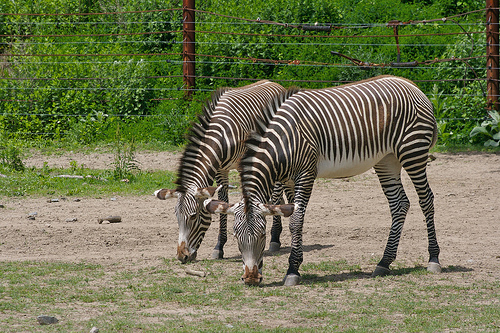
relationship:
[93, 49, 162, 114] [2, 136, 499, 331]
shrub on ground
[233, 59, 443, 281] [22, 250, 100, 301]
zebra grazing on grass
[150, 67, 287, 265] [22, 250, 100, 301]
zebra grazing on grass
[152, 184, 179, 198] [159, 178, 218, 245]
ear on head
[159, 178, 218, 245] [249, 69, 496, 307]
head of zebra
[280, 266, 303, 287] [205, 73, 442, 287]
hoof of zebra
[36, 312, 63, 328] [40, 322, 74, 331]
rock on ground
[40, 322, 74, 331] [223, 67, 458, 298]
ground in front of zebra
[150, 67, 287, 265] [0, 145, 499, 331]
zebra in field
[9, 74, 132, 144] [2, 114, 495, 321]
shrub in ground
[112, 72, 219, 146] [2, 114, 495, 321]
shrub in ground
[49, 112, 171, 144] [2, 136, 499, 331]
shrub growing from ground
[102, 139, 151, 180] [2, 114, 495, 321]
shrub growing from ground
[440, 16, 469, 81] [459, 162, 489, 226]
shrub growing from ground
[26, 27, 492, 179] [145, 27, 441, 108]
fence with support pole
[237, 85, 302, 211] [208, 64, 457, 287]
mane of zebra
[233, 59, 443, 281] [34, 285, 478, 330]
zebra grazing in field